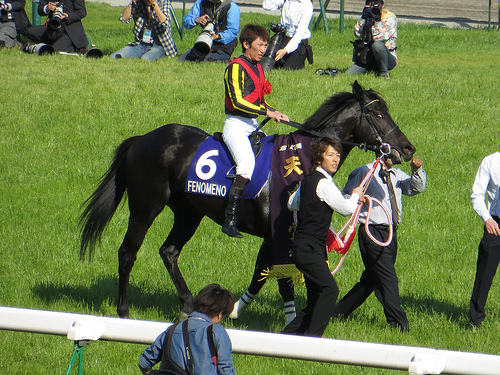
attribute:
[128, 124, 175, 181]
fur — black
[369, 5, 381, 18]
lens — large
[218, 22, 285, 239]
jockey — male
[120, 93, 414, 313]
horse — black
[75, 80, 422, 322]
horse — Black 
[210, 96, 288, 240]
pants — white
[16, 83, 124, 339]
grass — green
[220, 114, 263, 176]
pants — white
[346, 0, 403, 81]
person — photographing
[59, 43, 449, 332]
horse — black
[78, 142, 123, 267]
tail — long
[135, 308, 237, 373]
shirt — blue